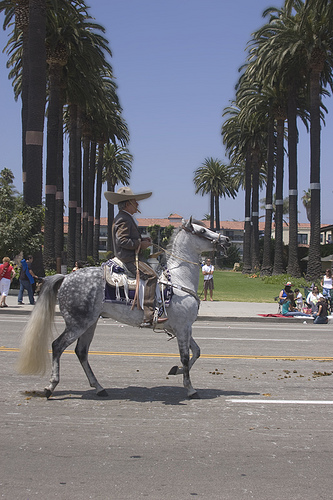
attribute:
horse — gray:
[48, 220, 238, 408]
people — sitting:
[254, 255, 331, 324]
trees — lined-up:
[214, 25, 327, 287]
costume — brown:
[108, 214, 170, 335]